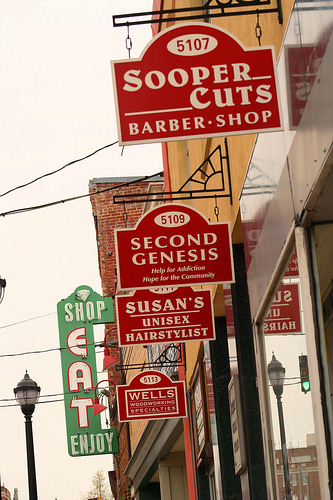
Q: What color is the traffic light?
A: Green.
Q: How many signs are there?
A: 5.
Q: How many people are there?
A: 0.